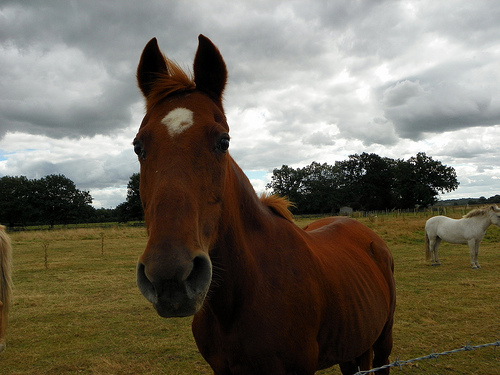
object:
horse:
[132, 34, 397, 374]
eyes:
[132, 138, 144, 159]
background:
[1, 116, 500, 300]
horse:
[425, 204, 500, 269]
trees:
[265, 152, 460, 211]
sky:
[0, 0, 498, 210]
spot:
[161, 106, 194, 139]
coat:
[425, 205, 499, 269]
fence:
[350, 338, 500, 375]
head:
[132, 33, 231, 319]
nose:
[136, 251, 213, 319]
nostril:
[182, 253, 211, 300]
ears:
[136, 37, 170, 99]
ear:
[193, 33, 228, 99]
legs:
[338, 353, 370, 374]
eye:
[215, 133, 230, 154]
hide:
[322, 246, 389, 368]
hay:
[0, 227, 13, 345]